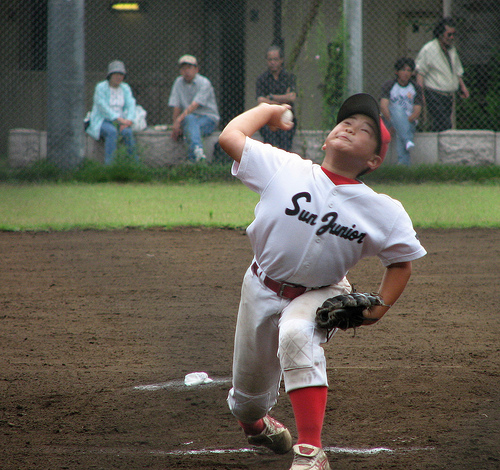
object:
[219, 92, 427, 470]
boy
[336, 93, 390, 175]
cap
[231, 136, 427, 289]
shirt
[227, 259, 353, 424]
pants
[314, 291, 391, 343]
glove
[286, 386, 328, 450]
socks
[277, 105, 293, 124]
ball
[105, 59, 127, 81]
hat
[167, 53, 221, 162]
man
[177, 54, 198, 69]
cap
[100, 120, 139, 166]
jeans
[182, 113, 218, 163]
jeans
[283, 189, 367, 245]
sun junior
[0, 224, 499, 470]
field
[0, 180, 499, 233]
grass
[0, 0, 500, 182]
fence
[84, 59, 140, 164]
spectators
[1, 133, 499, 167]
wall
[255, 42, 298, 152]
man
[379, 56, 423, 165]
man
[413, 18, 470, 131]
man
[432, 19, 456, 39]
hair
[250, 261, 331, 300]
belt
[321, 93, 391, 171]
head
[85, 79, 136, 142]
jacket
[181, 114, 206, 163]
legs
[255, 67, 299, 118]
shirt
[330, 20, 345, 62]
vines